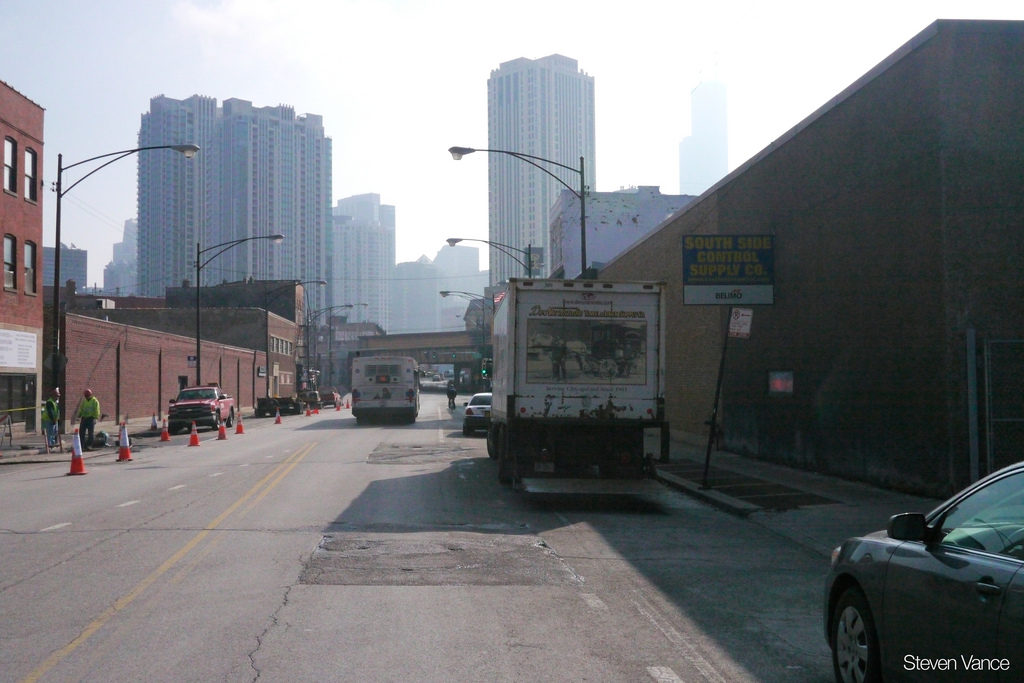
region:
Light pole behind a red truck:
[177, 225, 289, 402]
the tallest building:
[475, 42, 606, 309]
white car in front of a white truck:
[456, 387, 510, 439]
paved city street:
[0, 381, 848, 680]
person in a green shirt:
[63, 381, 106, 457]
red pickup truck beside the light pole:
[162, 375, 245, 430]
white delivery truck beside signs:
[478, 266, 684, 527]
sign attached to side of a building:
[668, 219, 783, 325]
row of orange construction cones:
[63, 387, 351, 485]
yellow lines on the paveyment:
[3, 435, 335, 679]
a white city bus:
[351, 356, 424, 423]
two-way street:
[11, 385, 860, 680]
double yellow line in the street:
[29, 442, 315, 678]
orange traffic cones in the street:
[68, 402, 356, 476]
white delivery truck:
[491, 279, 670, 505]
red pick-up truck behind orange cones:
[169, 383, 234, 422]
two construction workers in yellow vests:
[43, 385, 97, 440]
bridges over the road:
[367, 329, 481, 361]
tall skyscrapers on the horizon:
[137, 60, 599, 330]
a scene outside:
[12, 3, 1011, 677]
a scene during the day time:
[3, 17, 997, 678]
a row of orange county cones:
[22, 373, 381, 501]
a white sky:
[9, 6, 1019, 281]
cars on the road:
[47, 282, 1021, 679]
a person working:
[55, 376, 117, 472]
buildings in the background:
[82, 36, 759, 340]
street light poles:
[26, 114, 606, 459]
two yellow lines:
[10, 414, 349, 680]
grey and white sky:
[222, 18, 400, 88]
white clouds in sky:
[254, 8, 395, 85]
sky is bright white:
[540, 11, 730, 62]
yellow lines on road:
[28, 400, 281, 670]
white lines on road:
[500, 508, 736, 651]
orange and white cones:
[54, 376, 250, 497]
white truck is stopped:
[491, 275, 688, 479]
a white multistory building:
[133, 89, 336, 282]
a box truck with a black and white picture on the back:
[484, 279, 675, 504]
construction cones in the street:
[57, 388, 318, 481]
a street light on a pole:
[45, 138, 211, 439]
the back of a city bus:
[352, 356, 420, 424]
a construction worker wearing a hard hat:
[74, 389, 106, 444]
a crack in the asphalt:
[231, 505, 337, 676]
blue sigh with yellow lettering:
[679, 220, 778, 318]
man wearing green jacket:
[72, 379, 105, 449]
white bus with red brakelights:
[352, 340, 425, 430]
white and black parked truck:
[475, 268, 678, 500]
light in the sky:
[344, 61, 465, 159]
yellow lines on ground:
[145, 470, 317, 617]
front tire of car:
[755, 541, 939, 678]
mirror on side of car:
[831, 464, 955, 585]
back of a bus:
[312, 347, 443, 452]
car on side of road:
[125, 347, 272, 472]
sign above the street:
[638, 200, 810, 352]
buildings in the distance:
[100, 41, 635, 292]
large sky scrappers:
[122, 22, 682, 408]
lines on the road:
[470, 495, 685, 670]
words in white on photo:
[884, 616, 1022, 678]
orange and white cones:
[13, 389, 295, 514]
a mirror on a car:
[875, 503, 956, 560]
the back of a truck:
[492, 263, 689, 510]